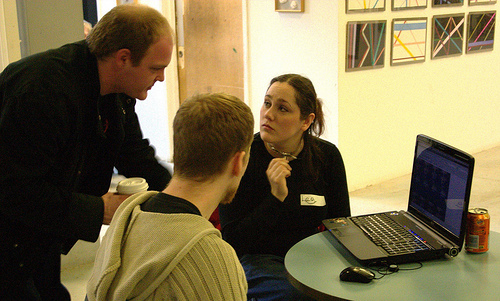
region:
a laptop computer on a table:
[281, 132, 484, 292]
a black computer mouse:
[332, 249, 436, 297]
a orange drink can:
[452, 186, 497, 267]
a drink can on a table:
[448, 200, 491, 295]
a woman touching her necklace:
[251, 65, 365, 189]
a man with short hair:
[151, 80, 258, 196]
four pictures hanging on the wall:
[337, 4, 492, 79]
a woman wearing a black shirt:
[242, 60, 344, 235]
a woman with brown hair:
[242, 63, 339, 143]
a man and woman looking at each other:
[66, 16, 332, 181]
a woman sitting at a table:
[222, 75, 359, 300]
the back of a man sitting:
[91, 93, 255, 299]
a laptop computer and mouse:
[325, 133, 466, 279]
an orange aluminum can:
[465, 206, 488, 252]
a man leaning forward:
[1, 3, 176, 298]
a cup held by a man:
[102, 175, 147, 230]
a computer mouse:
[339, 265, 376, 285]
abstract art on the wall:
[345, 20, 387, 65]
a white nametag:
[298, 193, 327, 205]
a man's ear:
[117, 48, 129, 71]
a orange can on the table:
[463, 205, 489, 257]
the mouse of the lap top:
[339, 266, 379, 284]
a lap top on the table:
[314, 137, 475, 267]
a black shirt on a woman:
[221, 134, 354, 250]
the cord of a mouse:
[368, 255, 418, 286]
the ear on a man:
[229, 148, 246, 181]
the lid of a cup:
[114, 171, 153, 201]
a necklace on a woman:
[265, 135, 301, 162]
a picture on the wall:
[338, 15, 384, 74]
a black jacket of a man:
[0, 35, 177, 257]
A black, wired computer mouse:
[339, 263, 379, 283]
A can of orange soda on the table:
[464, 205, 490, 256]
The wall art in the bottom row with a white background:
[389, 18, 429, 66]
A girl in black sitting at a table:
[249, 64, 351, 299]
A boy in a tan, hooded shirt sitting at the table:
[98, 100, 252, 299]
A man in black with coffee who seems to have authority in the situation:
[2, 9, 175, 299]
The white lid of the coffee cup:
[114, 175, 147, 192]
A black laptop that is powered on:
[327, 122, 469, 261]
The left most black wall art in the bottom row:
[345, 21, 387, 68]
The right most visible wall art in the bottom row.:
[467, 8, 498, 57]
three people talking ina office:
[8, 2, 353, 299]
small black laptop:
[317, 130, 479, 273]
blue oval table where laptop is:
[282, 203, 499, 299]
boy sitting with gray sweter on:
[78, 89, 243, 299]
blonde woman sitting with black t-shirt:
[235, 71, 352, 291]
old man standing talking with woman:
[3, 2, 174, 299]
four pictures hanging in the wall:
[349, 0, 499, 68]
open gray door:
[25, 4, 102, 233]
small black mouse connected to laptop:
[338, 263, 410, 284]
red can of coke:
[465, 203, 488, 254]